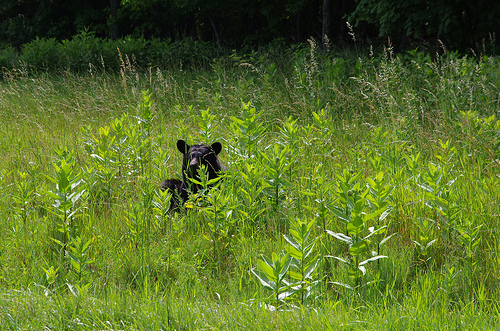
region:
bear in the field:
[75, 100, 270, 227]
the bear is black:
[192, 143, 240, 169]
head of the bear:
[180, 144, 206, 176]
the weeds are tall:
[308, 149, 405, 262]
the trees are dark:
[198, 12, 344, 53]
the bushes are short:
[6, 16, 148, 61]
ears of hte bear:
[171, 135, 218, 150]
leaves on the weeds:
[70, 107, 108, 178]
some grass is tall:
[130, 280, 185, 328]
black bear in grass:
[149, 129, 246, 222]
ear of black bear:
[173, 130, 192, 152]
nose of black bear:
[184, 158, 201, 175]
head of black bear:
[173, 127, 230, 178]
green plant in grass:
[258, 245, 300, 303]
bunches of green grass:
[386, 301, 423, 329]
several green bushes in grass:
[34, 28, 108, 71]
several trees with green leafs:
[258, 0, 455, 60]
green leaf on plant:
[255, 250, 277, 277]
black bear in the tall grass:
[138, 127, 225, 214]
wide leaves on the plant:
[246, 215, 317, 310]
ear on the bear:
[208, 135, 220, 159]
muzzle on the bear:
[185, 160, 200, 177]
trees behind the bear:
[11, 9, 433, 71]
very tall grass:
[285, 84, 418, 262]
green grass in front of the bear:
[99, 293, 201, 329]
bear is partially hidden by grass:
[144, 130, 241, 222]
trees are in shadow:
[125, 8, 307, 43]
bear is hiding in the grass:
[114, 124, 247, 259]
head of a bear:
[165, 128, 223, 184]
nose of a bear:
[189, 151, 206, 168]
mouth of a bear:
[183, 164, 208, 176]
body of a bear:
[136, 176, 193, 221]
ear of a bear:
[170, 135, 185, 147]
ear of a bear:
[205, 135, 238, 157]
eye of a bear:
[194, 150, 211, 163]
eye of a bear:
[185, 147, 193, 156]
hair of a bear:
[191, 144, 205, 152]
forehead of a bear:
[186, 145, 211, 155]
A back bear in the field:
[141, 120, 233, 191]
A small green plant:
[268, 210, 326, 288]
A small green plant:
[38, 149, 108, 299]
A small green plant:
[325, 164, 370, 304]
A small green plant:
[417, 127, 457, 245]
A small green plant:
[254, 127, 292, 215]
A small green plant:
[287, 99, 352, 177]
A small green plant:
[125, 72, 169, 187]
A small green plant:
[74, 117, 129, 215]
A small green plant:
[62, 27, 107, 74]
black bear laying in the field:
[143, 135, 246, 233]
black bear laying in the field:
[146, 136, 237, 209]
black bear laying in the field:
[140, 134, 237, 211]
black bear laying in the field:
[127, 135, 262, 216]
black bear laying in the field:
[140, 131, 245, 212]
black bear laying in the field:
[136, 132, 252, 217]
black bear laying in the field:
[123, 131, 253, 218]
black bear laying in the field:
[134, 135, 241, 215]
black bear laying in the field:
[153, 134, 238, 200]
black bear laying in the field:
[131, 138, 236, 206]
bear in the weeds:
[149, 132, 244, 210]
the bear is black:
[149, 123, 249, 223]